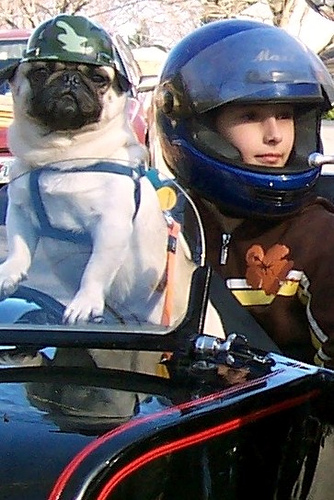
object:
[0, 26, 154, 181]
car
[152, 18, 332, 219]
helmet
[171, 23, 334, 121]
face shield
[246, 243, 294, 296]
flower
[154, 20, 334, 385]
girl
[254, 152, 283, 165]
mouth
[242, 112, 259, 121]
eye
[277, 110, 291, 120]
eye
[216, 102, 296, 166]
face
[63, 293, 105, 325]
paw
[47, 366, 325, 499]
stripe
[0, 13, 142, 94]
hat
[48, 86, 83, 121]
mouth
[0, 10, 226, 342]
dog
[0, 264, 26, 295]
paws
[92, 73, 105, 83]
eye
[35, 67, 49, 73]
eye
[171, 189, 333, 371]
brown jacket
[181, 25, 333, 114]
shield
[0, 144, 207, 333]
windshield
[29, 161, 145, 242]
harness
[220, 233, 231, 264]
zipper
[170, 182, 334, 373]
sweater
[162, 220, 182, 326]
leash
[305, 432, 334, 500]
concrete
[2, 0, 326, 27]
trees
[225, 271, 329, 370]
stripe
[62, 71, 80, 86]
nose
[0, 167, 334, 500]
car